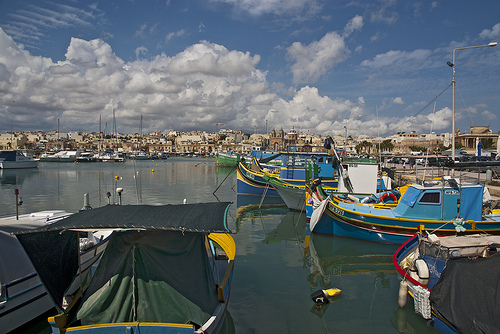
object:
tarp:
[66, 229, 214, 326]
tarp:
[10, 203, 241, 239]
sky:
[0, 0, 499, 133]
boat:
[301, 177, 498, 245]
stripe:
[345, 208, 490, 223]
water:
[0, 158, 461, 334]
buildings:
[451, 125, 497, 148]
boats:
[392, 223, 499, 334]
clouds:
[287, 14, 365, 86]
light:
[12, 186, 25, 219]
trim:
[388, 237, 416, 290]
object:
[293, 300, 400, 325]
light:
[446, 43, 497, 162]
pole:
[451, 49, 456, 173]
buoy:
[310, 287, 330, 307]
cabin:
[404, 191, 450, 221]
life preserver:
[376, 192, 397, 207]